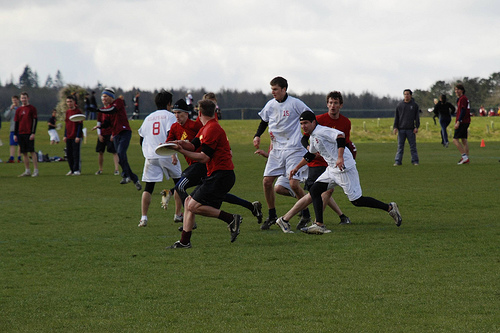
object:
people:
[165, 97, 263, 232]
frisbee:
[154, 142, 178, 155]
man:
[286, 108, 403, 229]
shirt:
[256, 95, 316, 151]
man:
[391, 87, 424, 166]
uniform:
[136, 109, 183, 181]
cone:
[479, 138, 485, 147]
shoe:
[227, 212, 244, 243]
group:
[0, 75, 407, 250]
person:
[164, 98, 244, 250]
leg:
[186, 177, 244, 245]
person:
[134, 90, 189, 228]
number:
[151, 121, 162, 135]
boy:
[252, 75, 316, 230]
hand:
[166, 144, 182, 151]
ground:
[1, 118, 498, 333]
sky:
[0, 0, 499, 101]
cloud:
[1, 2, 495, 98]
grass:
[0, 116, 498, 332]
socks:
[352, 195, 390, 212]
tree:
[18, 63, 41, 88]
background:
[1, 0, 500, 121]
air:
[0, 0, 500, 333]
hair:
[270, 75, 290, 92]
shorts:
[188, 169, 236, 210]